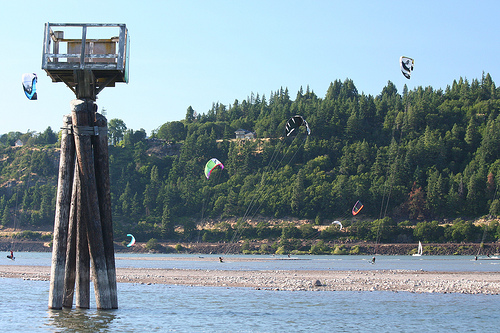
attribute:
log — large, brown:
[66, 105, 116, 314]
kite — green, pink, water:
[202, 156, 224, 178]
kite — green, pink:
[169, 132, 246, 193]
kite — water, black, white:
[398, 56, 417, 83]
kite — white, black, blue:
[391, 51, 417, 84]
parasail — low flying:
[124, 229, 138, 249]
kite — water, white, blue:
[19, 70, 39, 102]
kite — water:
[285, 114, 312, 137]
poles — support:
[41, 99, 140, 316]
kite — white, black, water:
[399, 54, 420, 81]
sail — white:
[418, 237, 423, 253]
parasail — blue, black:
[16, 72, 53, 109]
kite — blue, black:
[15, 64, 47, 106]